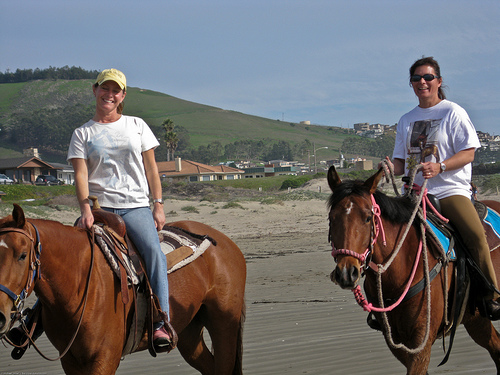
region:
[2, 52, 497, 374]
two women on horses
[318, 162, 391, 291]
the head of a horse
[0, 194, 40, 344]
the head of a horse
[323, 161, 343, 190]
the ear of a horse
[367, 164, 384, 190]
the ear of a horse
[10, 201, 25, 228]
the ear of a horse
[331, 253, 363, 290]
the nose of a horse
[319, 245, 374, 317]
the bridle of a horse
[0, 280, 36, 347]
the bridle of a horse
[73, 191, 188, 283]
the saddle of a horse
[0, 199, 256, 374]
short haired brown horse wearing a saddle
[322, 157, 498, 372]
short haired brown horse wearing a saddle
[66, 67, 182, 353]
lady wearing a white tee shirt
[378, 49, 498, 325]
lady wearing a white tee shirt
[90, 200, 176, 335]
light blue denim pants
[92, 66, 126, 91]
pale yellow base ball cap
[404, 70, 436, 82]
black sun glasses with oval lenses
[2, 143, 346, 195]
grouping of small residential homes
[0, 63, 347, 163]
dark green trees atop a hill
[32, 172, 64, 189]
parked black subaru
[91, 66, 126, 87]
a yellow cap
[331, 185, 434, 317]
pink reins for a horse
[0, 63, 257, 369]
a woman in a cap riding a horse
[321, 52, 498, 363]
a woman in shades riding a horse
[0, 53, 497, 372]
two women riding horses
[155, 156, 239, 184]
a one story house with a red roof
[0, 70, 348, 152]
a long sloping hill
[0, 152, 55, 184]
a house with a black roof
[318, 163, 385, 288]
a horse head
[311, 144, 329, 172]
a distant street light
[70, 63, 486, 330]
the woman is on a horse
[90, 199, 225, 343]
the woman is wearing jeans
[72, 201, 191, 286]
the woman is on a saddle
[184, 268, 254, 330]
the horse is brown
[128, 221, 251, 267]
a blanket is on a saddle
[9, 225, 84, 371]
the horse is wearing a harness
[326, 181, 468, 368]
the horse has a pink harness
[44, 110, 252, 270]
the woman is wearing a t-shirt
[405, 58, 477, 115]
the woman is wearing sunglasses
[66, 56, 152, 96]
the woman is wearing a hat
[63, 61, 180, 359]
The woman is smiling.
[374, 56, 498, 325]
The woman is smiling.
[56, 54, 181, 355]
The woman is wearing a cap.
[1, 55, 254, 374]
The woman is riding a horse.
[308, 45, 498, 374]
The woman is riding a horse.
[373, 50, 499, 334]
The woman is wearing sunglasses.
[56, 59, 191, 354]
The woman is wearing a watch on her left wrist.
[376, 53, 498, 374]
The woman is wearing a watch on her left wrist.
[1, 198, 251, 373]
The horse is brown and white.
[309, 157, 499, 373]
The horse is brown and white.